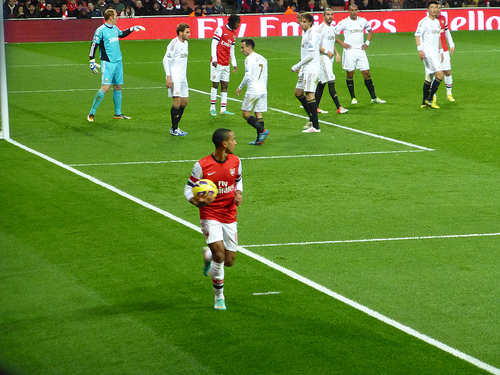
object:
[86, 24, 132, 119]
outfit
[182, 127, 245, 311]
man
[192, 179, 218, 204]
ball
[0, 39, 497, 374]
grass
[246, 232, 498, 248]
lines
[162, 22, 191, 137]
player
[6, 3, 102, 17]
spectator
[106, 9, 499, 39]
wall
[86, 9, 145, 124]
uniform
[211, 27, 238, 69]
uniform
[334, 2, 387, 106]
male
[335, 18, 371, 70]
white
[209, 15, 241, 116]
guy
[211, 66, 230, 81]
white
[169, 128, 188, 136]
shoe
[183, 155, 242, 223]
shirt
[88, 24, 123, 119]
blue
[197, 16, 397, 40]
logo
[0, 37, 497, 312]
soccer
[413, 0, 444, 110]
teammate